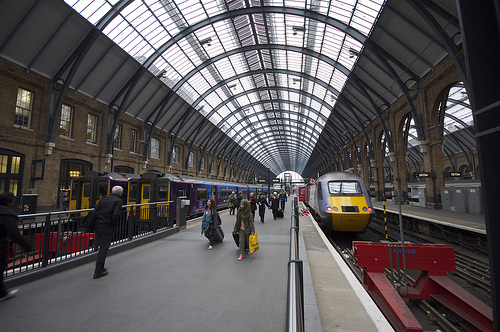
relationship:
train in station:
[301, 170, 376, 234] [1, 0, 494, 330]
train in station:
[122, 170, 285, 224] [1, 0, 494, 330]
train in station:
[100, 174, 137, 219] [1, 0, 494, 330]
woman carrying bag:
[231, 197, 261, 260] [247, 233, 258, 257]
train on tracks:
[301, 170, 376, 234] [336, 227, 461, 331]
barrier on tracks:
[350, 191, 494, 331] [336, 227, 461, 331]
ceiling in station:
[64, 0, 384, 175] [1, 0, 494, 330]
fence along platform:
[8, 200, 174, 280] [5, 192, 292, 331]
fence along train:
[8, 200, 174, 280] [122, 170, 285, 224]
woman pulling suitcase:
[201, 196, 220, 251] [205, 224, 223, 244]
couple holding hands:
[256, 191, 280, 223] [267, 205, 272, 212]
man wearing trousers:
[90, 185, 126, 279] [93, 230, 111, 270]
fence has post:
[8, 200, 174, 280] [41, 212, 50, 268]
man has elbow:
[2, 190, 35, 302] [10, 231, 24, 245]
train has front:
[301, 170, 376, 234] [322, 170, 371, 236]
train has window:
[301, 170, 376, 234] [325, 178, 360, 196]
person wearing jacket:
[278, 187, 290, 211] [278, 191, 287, 202]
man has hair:
[90, 185, 126, 279] [112, 185, 123, 194]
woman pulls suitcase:
[201, 196, 220, 251] [205, 224, 223, 244]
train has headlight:
[301, 170, 376, 234] [361, 204, 369, 213]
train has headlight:
[301, 170, 376, 234] [335, 208, 336, 210]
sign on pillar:
[413, 170, 430, 180] [414, 100, 445, 209]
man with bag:
[269, 190, 279, 219] [275, 207, 285, 220]